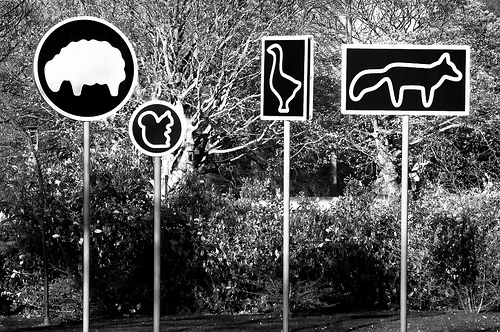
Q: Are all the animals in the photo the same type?
A: No, they are sheep and squirrels.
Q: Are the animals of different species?
A: Yes, they are sheep and squirrels.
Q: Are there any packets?
A: No, there are no packets.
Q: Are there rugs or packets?
A: No, there are no packets or rugs.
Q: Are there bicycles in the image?
A: No, there are no bicycles.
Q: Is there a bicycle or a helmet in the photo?
A: No, there are no bicycles or helmets.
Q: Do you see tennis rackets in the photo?
A: No, there are no tennis rackets.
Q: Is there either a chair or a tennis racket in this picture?
A: No, there are no rackets or chairs.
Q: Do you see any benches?
A: No, there are no benches.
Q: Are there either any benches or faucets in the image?
A: No, there are no benches or faucets.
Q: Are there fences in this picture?
A: No, there are no fences.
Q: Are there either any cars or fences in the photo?
A: No, there are no fences or cars.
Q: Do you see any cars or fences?
A: No, there are no fences or cars.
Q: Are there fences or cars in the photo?
A: No, there are no fences or cars.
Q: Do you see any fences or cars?
A: No, there are no fences or cars.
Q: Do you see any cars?
A: No, there are no cars.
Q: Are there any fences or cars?
A: No, there are no cars or fences.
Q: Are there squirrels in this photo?
A: Yes, there is a squirrel.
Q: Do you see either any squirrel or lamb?
A: Yes, there is a squirrel.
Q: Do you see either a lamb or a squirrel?
A: Yes, there is a squirrel.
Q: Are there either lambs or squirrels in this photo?
A: Yes, there is a squirrel.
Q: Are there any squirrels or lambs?
A: Yes, there is a squirrel.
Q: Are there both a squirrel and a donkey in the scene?
A: No, there is a squirrel but no donkeys.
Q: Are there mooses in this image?
A: No, there are no mooses.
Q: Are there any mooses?
A: No, there are no mooses.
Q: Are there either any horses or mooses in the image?
A: No, there are no mooses or horses.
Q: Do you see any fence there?
A: No, there are no fences.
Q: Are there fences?
A: No, there are no fences.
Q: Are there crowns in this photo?
A: No, there are no crowns.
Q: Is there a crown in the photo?
A: No, there are no crowns.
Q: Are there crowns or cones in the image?
A: No, there are no crowns or cones.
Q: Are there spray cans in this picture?
A: No, there are no spray cans.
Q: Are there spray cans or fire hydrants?
A: No, there are no spray cans or fire hydrants.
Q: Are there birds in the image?
A: Yes, there is a bird.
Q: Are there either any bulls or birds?
A: Yes, there is a bird.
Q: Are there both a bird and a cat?
A: No, there is a bird but no cats.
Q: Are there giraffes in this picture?
A: No, there are no giraffes.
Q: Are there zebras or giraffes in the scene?
A: No, there are no giraffes or zebras.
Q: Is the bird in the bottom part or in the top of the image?
A: The bird is in the top of the image.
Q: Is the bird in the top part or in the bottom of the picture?
A: The bird is in the top of the image.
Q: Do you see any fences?
A: No, there are no fences.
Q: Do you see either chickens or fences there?
A: No, there are no fences or chickens.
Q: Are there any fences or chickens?
A: No, there are no fences or chickens.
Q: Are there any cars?
A: No, there are no cars.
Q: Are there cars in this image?
A: No, there are no cars.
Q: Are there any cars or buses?
A: No, there are no cars or buses.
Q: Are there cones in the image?
A: No, there are no cones.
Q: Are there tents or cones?
A: No, there are no cones or tents.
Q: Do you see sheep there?
A: Yes, there is a sheep.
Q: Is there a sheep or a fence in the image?
A: Yes, there is a sheep.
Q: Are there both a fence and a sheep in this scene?
A: No, there is a sheep but no fences.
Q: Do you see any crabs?
A: No, there are no crabs.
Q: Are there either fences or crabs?
A: No, there are no crabs or fences.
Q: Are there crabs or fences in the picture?
A: No, there are no crabs or fences.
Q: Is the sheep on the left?
A: Yes, the sheep is on the left of the image.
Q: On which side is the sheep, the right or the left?
A: The sheep is on the left of the image.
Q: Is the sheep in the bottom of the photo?
A: No, the sheep is in the top of the image.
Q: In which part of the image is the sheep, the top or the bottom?
A: The sheep is in the top of the image.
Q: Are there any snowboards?
A: No, there are no snowboards.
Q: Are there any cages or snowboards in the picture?
A: No, there are no snowboards or cages.